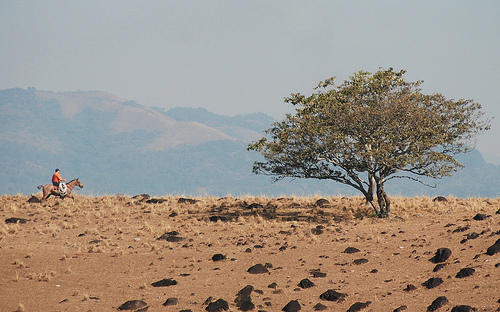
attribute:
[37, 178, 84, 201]
horse — big, brown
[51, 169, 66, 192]
rider — orange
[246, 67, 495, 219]
tree — lone, large, green, solitary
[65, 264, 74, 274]
grass patch — brown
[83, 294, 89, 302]
grass patch — brown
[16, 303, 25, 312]
grass patch — brown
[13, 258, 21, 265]
grass patch — brown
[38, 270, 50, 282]
grass patch — brown, dead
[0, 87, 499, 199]
mountain range — distant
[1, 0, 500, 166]
sky — grey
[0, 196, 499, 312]
ground — dirt, dry, hilly, rocky, brown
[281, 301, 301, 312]
rock — dark, medium sized, black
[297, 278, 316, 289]
rock — dark, medium sized, black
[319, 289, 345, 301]
rock — dark, medium sized, black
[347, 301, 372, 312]
rock — dark, medium sized, black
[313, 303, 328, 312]
rock — dark, black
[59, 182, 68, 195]
rope — white, coiled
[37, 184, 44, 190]
tail — short, chopped off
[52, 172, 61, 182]
shirt — orange, bright orange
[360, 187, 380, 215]
trunk — small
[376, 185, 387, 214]
trunk — small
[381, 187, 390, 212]
trunk — small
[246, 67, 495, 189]
top — dry, bushy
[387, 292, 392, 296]
rock — small sized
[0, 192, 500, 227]
grassy area — thick, dry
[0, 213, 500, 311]
sandy area — dry, bare